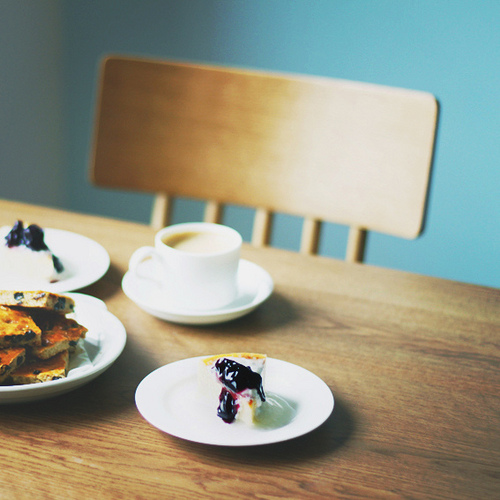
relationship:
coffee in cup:
[183, 233, 228, 254] [156, 235, 245, 290]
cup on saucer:
[156, 235, 245, 290] [133, 282, 285, 320]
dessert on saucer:
[12, 219, 68, 272] [61, 224, 107, 282]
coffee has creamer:
[183, 233, 228, 254] [192, 233, 213, 249]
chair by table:
[109, 57, 452, 224] [310, 261, 493, 354]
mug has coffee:
[137, 222, 228, 306] [183, 233, 228, 254]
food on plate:
[216, 350, 290, 419] [140, 367, 362, 453]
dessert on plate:
[12, 219, 68, 272] [11, 218, 107, 290]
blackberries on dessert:
[4, 216, 49, 254] [12, 219, 68, 272]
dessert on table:
[12, 219, 68, 272] [310, 261, 493, 354]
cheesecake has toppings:
[205, 355, 270, 413] [209, 362, 258, 388]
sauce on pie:
[30, 229, 44, 241] [13, 216, 86, 296]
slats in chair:
[190, 203, 319, 249] [109, 57, 452, 224]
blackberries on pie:
[13, 216, 49, 254] [13, 216, 86, 296]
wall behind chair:
[265, 28, 479, 86] [109, 57, 452, 224]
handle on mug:
[127, 243, 156, 299] [137, 222, 228, 306]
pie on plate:
[13, 216, 86, 296] [11, 218, 107, 290]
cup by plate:
[156, 235, 245, 290] [140, 367, 362, 453]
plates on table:
[19, 227, 300, 462] [310, 261, 493, 354]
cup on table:
[156, 235, 245, 290] [310, 261, 493, 354]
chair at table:
[109, 57, 452, 224] [310, 261, 493, 354]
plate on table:
[140, 367, 362, 453] [310, 261, 493, 354]